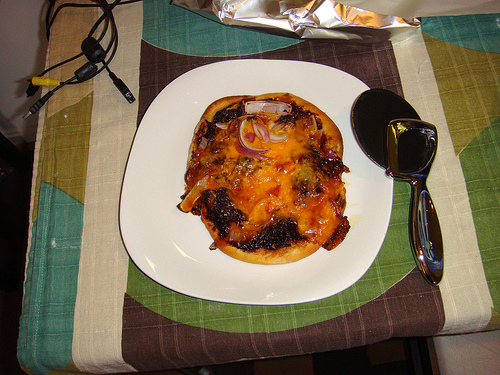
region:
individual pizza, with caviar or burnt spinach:
[170, 87, 360, 274]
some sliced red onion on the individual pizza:
[223, 100, 292, 155]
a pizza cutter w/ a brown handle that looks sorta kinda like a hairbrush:
[346, 82, 457, 300]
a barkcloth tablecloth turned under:
[25, 3, 497, 363]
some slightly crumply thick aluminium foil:
[160, 0, 422, 49]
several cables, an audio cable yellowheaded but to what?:
[14, 1, 163, 130]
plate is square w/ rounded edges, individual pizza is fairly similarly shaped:
[111, 55, 393, 312]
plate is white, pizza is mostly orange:
[115, 53, 407, 313]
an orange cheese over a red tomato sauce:
[240, 132, 307, 218]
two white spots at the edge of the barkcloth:
[44, 104, 75, 269]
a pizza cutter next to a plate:
[344, 73, 454, 291]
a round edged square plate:
[114, 47, 435, 313]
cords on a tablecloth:
[13, 1, 150, 129]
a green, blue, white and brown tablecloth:
[9, 1, 498, 367]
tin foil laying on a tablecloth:
[167, 0, 428, 52]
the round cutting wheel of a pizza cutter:
[347, 77, 433, 177]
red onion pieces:
[232, 95, 279, 155]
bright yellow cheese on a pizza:
[251, 140, 291, 206]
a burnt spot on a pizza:
[246, 215, 296, 250]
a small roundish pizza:
[182, 90, 363, 271]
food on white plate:
[187, 90, 344, 269]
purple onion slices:
[230, 95, 285, 162]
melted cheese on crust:
[202, 108, 329, 239]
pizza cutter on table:
[345, 85, 447, 287]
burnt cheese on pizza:
[203, 191, 299, 251]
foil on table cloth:
[183, 0, 423, 51]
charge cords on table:
[17, 0, 147, 125]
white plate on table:
[120, 60, 377, 310]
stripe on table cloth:
[67, 0, 147, 368]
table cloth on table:
[32, 2, 493, 369]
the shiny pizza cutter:
[352, 87, 444, 284]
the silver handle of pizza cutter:
[410, 177, 445, 283]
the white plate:
[119, 57, 392, 304]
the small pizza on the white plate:
[183, 94, 345, 254]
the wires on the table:
[24, 5, 136, 111]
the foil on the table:
[169, 0, 421, 40]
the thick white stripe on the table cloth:
[72, 122, 124, 357]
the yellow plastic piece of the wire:
[24, 76, 61, 86]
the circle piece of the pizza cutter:
[352, 88, 428, 169]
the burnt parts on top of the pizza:
[204, 191, 301, 249]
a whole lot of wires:
[24, 14, 156, 125]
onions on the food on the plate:
[227, 116, 287, 162]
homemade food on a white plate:
[171, 79, 349, 274]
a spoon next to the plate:
[367, 119, 471, 285]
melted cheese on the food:
[225, 157, 345, 224]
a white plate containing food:
[84, 37, 401, 318]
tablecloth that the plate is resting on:
[50, 244, 134, 331]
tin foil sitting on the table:
[210, 5, 433, 51]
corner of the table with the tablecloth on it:
[5, 224, 132, 364]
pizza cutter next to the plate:
[339, 67, 458, 293]